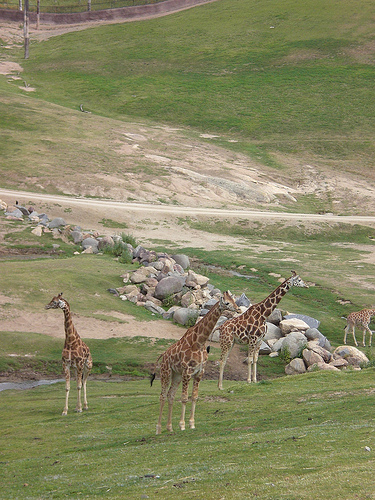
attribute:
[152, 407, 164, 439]
leg — white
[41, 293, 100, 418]
giraffe — large, tan, brown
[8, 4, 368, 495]
green grass — green 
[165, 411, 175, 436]
white leg — white 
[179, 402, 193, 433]
leg — white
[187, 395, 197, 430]
leg — white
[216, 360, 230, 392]
leg — white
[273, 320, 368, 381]
rocks — grey, large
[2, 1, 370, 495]
grass — short, light green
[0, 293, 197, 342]
sand — light brown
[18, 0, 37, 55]
tree — long, thin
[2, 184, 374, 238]
roadway — long, dirt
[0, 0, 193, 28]
wall — long, grey, concrete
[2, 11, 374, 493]
area — grassy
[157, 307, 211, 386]
spots — brown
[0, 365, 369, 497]
grass — green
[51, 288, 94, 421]
giraffe — white, brown, spotted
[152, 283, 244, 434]
giraffe — spotted, brown, white